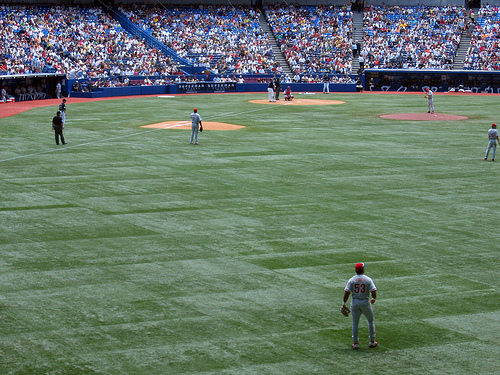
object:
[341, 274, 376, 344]
uniform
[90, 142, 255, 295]
field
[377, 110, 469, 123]
mound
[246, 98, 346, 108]
plate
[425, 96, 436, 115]
pants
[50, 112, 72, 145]
black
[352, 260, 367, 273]
cap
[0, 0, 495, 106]
outfield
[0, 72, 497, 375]
inside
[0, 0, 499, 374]
stadium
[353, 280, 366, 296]
53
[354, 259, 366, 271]
red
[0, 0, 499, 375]
baseball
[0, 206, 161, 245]
patch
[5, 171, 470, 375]
field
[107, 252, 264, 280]
patch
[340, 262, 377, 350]
baseball player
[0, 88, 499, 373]
field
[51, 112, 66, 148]
man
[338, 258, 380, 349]
man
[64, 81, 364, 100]
wall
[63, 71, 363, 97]
stands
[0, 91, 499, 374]
grass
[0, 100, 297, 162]
line